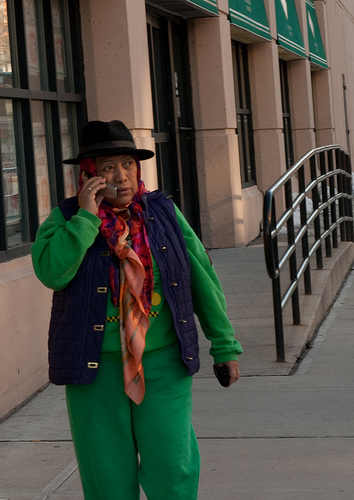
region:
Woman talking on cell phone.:
[74, 123, 142, 204]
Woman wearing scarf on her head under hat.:
[78, 125, 161, 265]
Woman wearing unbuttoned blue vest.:
[42, 121, 210, 389]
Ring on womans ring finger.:
[78, 170, 104, 218]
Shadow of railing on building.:
[201, 188, 247, 245]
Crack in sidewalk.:
[208, 400, 352, 460]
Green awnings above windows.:
[230, 0, 333, 69]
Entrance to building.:
[149, 5, 242, 247]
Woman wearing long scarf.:
[63, 116, 188, 411]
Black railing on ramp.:
[249, 145, 349, 365]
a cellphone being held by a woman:
[80, 172, 117, 200]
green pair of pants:
[62, 339, 200, 498]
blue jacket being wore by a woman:
[50, 192, 199, 383]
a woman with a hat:
[31, 119, 240, 499]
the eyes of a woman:
[101, 160, 133, 172]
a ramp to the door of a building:
[194, 240, 352, 374]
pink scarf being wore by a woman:
[80, 193, 151, 405]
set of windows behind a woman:
[0, 2, 91, 251]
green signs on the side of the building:
[192, 0, 330, 70]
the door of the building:
[145, 16, 177, 206]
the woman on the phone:
[58, 118, 161, 321]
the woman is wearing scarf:
[75, 192, 165, 413]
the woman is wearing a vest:
[49, 226, 229, 395]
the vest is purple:
[48, 274, 250, 427]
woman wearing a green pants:
[84, 332, 221, 494]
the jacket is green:
[12, 200, 242, 406]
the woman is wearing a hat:
[71, 110, 163, 184]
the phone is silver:
[78, 164, 126, 216]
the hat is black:
[65, 122, 156, 185]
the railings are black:
[247, 143, 333, 395]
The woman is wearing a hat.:
[25, 110, 254, 395]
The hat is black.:
[54, 109, 155, 171]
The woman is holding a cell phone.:
[25, 111, 177, 287]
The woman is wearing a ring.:
[29, 109, 153, 288]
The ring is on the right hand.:
[23, 111, 157, 292]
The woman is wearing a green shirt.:
[28, 111, 246, 389]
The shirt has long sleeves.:
[18, 188, 256, 385]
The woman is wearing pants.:
[19, 109, 250, 498]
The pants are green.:
[63, 337, 203, 499]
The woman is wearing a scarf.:
[28, 117, 241, 408]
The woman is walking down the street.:
[36, 112, 258, 496]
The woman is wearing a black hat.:
[57, 110, 161, 212]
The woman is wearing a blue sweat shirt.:
[25, 184, 249, 366]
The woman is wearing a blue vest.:
[41, 192, 203, 385]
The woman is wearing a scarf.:
[96, 206, 164, 406]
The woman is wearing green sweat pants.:
[51, 354, 215, 496]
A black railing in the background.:
[258, 138, 347, 365]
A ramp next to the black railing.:
[175, 235, 293, 374]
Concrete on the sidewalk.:
[211, 399, 344, 496]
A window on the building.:
[3, 1, 96, 248]